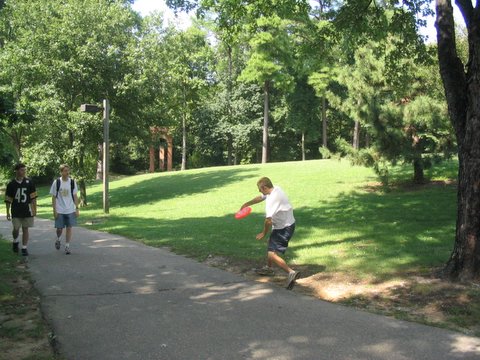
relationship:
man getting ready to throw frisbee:
[231, 172, 302, 291] [242, 181, 248, 227]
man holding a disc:
[231, 172, 302, 291] [232, 205, 251, 220]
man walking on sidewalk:
[47, 163, 80, 251] [18, 164, 255, 347]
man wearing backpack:
[44, 171, 109, 251] [44, 171, 77, 219]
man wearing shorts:
[47, 163, 80, 251] [53, 205, 90, 229]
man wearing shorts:
[229, 179, 331, 291] [236, 238, 307, 270]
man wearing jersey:
[3, 162, 42, 287] [3, 162, 42, 287]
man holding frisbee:
[231, 172, 302, 291] [214, 166, 293, 268]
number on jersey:
[8, 181, 42, 215] [8, 181, 42, 215]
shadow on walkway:
[15, 191, 441, 322] [15, 191, 441, 322]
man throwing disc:
[231, 172, 302, 291] [220, 180, 264, 234]